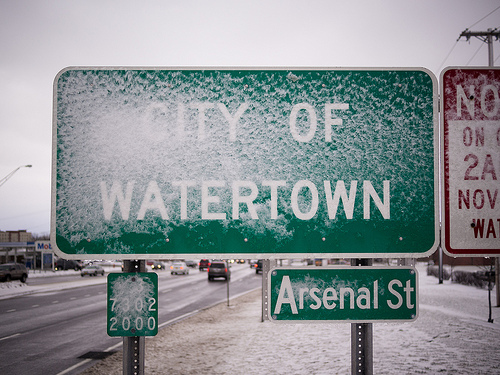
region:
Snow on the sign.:
[55, 67, 438, 258]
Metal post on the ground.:
[347, 260, 376, 371]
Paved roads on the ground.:
[0, 263, 287, 373]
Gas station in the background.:
[2, 238, 59, 272]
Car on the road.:
[202, 262, 234, 283]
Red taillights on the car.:
[166, 263, 188, 273]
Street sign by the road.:
[437, 65, 498, 262]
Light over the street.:
[2, 155, 35, 193]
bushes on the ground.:
[424, 260, 487, 290]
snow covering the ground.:
[62, 270, 497, 374]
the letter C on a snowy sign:
[141, 98, 167, 144]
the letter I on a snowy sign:
[173, 98, 189, 148]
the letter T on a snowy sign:
[187, 100, 218, 140]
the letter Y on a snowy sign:
[216, 99, 249, 141]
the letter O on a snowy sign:
[288, 99, 315, 144]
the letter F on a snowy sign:
[321, 99, 348, 143]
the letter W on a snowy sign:
[97, 178, 137, 222]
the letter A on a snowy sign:
[135, 177, 170, 225]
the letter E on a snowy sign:
[197, 178, 229, 220]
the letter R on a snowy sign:
[228, 177, 260, 219]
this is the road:
[32, 316, 67, 333]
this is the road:
[12, 309, 67, 351]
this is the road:
[167, 288, 205, 310]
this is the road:
[165, 272, 210, 303]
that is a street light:
[20, 153, 34, 173]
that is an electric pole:
[462, 16, 489, 67]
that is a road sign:
[55, 88, 429, 248]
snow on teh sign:
[87, 63, 365, 250]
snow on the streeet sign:
[80, 53, 399, 294]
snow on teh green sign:
[71, 63, 404, 298]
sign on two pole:
[51, 50, 478, 343]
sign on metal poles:
[51, 30, 417, 367]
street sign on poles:
[67, 21, 442, 362]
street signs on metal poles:
[46, 30, 372, 366]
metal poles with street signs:
[30, 23, 421, 371]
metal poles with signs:
[30, 32, 450, 369]